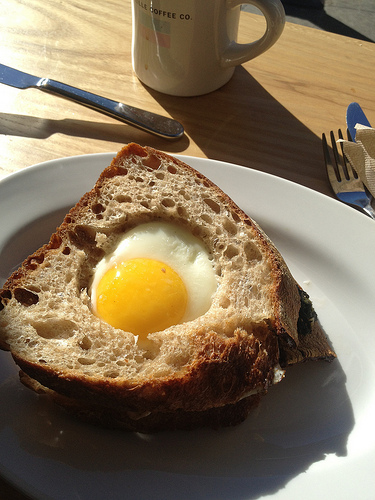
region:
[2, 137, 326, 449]
A breakfast sandwich on a white plate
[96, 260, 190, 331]
An unbroken yellow egg yolk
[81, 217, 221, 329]
An egg inside of the bread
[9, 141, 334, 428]
An egg sandwich on the plate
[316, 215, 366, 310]
A white plate beneath the sandwich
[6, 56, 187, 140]
A silver knife behind the plate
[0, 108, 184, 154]
The black shadow of the knife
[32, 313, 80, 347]
A small hole in the bread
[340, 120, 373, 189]
A white napkin by the fork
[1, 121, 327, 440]
Egg in a hole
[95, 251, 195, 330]
Yellow yolk of egg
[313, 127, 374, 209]
Silver fork on the side of a plate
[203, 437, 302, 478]
Shadow on plate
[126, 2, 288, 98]
Coffee cup beside plate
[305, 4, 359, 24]
Shadow on the floor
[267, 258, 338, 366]
Crust of bread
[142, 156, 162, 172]
whole in the bread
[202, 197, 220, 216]
whole in the bread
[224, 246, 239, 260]
whole in the bread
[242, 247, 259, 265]
whole in the bread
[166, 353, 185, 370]
whole in the bread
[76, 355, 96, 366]
whole in the bread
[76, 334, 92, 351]
whole in the bread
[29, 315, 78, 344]
whole in the bread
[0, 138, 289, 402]
a piece of bread with egg in side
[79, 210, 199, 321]
a cooked egg in the center of a slice of bread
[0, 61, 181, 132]
a knife on a table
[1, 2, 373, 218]
a light brown wooden table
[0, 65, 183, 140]
a knife on a table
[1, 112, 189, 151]
the shadow of a knife on a table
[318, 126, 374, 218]
a fork on a table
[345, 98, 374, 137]
a knife wrapped in a napkin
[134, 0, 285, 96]
a white coffee mug on a table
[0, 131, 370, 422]
The plate contains breakfast.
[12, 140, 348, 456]
The egg is cooked into the bread.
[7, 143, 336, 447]
The bread is brown.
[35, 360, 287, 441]
The crust is brown.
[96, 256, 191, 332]
The egg yolk is yellow.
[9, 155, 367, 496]
The plate is white.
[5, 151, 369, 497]
The plate is ceramic.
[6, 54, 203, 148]
The knife is silver.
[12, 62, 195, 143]
The knife is shiny.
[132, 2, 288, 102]
The coffee cup is white.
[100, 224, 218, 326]
egg in bread bowl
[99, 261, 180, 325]
yellow yolk in egg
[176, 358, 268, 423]
golden brown crust on bread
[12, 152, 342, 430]
bread on white plate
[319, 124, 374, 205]
silver fork on table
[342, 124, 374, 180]
white napkin on table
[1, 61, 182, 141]
silver knife on table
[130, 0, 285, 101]
white coffee mug on table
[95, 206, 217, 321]
egg inside the bread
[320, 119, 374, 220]
fork on the table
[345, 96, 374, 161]
knife on the table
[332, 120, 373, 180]
napkin on the table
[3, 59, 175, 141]
silver knife on the table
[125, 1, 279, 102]
white mug on the table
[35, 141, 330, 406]
bread on the plate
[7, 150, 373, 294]
white plate on the table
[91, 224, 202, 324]
egg in side the bread